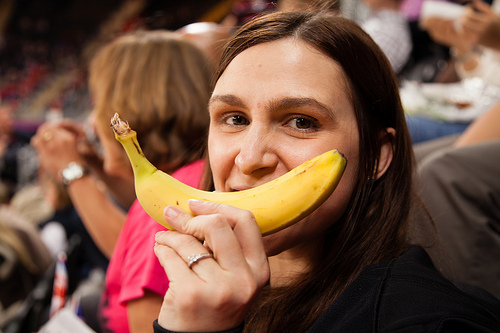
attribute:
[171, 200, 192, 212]
spot — BROWN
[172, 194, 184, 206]
spot — brown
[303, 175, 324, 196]
spot — brown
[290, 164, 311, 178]
spot — brown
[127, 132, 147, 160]
spot — brown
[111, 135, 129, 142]
spot — brown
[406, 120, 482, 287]
pants — grey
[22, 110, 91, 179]
hand — man's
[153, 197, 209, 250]
nail — pink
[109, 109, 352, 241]
banana — yellow, ripe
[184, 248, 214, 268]
ring — engagement ring, wedding ring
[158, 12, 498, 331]
woman — holding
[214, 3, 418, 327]
hair — brown, dark, straight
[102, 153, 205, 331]
shirt — pink, black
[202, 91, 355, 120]
eyebrow — brown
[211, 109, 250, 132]
eye — dark, brown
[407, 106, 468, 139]
jean — blue